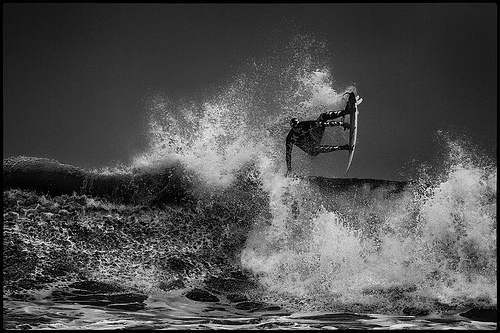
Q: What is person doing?
A: Surfing.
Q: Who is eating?
A: No one.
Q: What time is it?
A: Daytime.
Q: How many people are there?
A: One.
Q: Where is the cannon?
A: No cannon.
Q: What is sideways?
A: Surfboard.